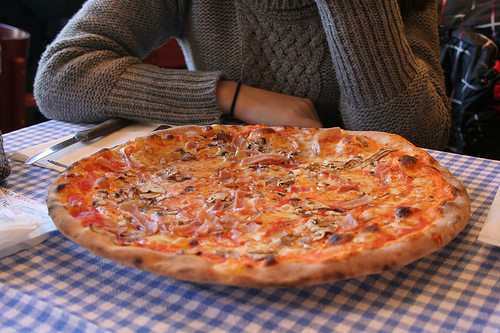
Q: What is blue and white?
A: Tablecloth.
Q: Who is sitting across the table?
A: One person.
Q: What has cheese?
A: A pizza.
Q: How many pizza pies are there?
A: One.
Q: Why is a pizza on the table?
A: To be eaten.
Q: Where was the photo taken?
A: In a restaurant.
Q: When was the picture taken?
A: Daytime.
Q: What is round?
A: Pizza pie.